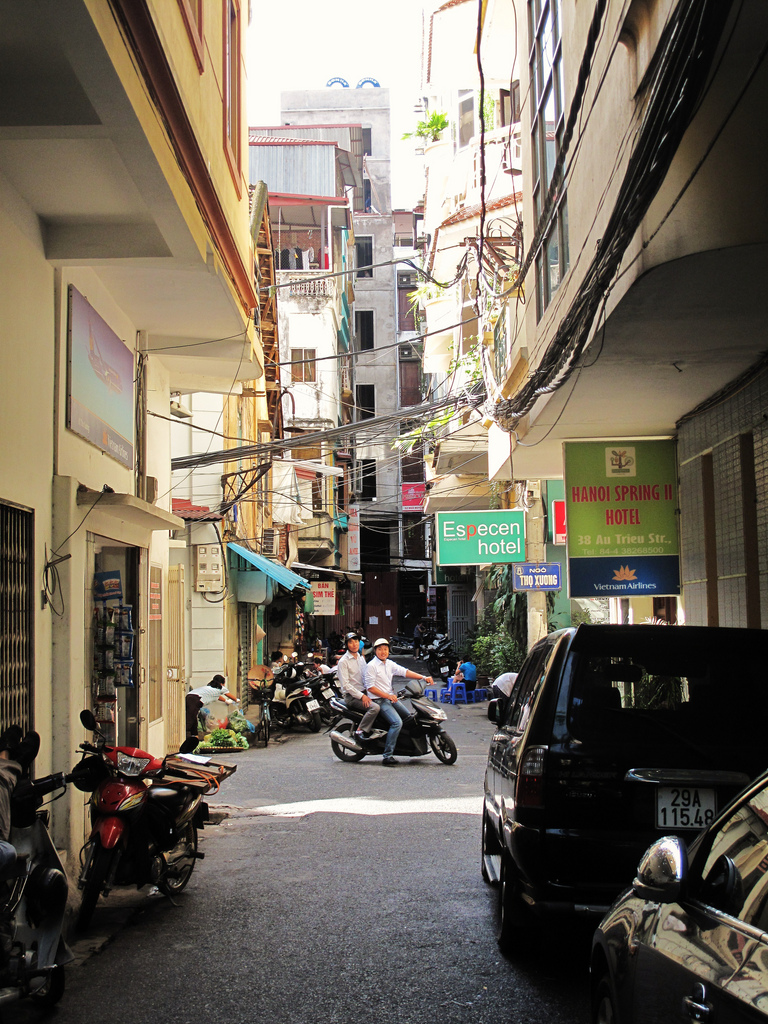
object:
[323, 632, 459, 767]
men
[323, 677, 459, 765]
motorbike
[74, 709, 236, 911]
motorbike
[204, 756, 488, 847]
street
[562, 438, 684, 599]
sign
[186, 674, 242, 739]
woman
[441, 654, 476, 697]
woman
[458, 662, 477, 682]
shirt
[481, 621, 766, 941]
van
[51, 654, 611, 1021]
street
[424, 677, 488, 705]
chairs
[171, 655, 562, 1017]
road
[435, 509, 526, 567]
sign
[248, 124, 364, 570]
building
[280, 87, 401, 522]
building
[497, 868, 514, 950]
tires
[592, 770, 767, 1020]
car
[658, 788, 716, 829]
plate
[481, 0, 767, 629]
hotel